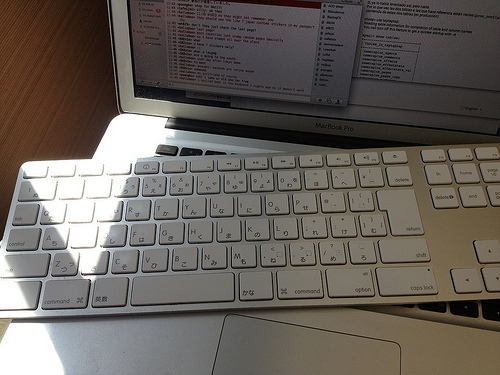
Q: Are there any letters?
A: Yes, there are letters.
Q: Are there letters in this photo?
A: Yes, there are letters.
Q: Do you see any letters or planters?
A: Yes, there are letters.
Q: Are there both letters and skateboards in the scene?
A: No, there are letters but no skateboards.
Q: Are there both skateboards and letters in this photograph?
A: No, there are letters but no skateboards.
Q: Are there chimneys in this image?
A: No, there are no chimneys.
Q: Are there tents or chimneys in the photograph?
A: No, there are no chimneys or tents.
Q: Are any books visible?
A: No, there are no books.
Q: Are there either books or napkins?
A: No, there are no books or napkins.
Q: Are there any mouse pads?
A: Yes, there is a mouse pad.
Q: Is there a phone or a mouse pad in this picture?
A: Yes, there is a mouse pad.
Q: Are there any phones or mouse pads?
A: Yes, there is a mouse pad.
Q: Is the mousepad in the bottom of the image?
A: Yes, the mousepad is in the bottom of the image.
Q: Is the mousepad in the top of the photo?
A: No, the mousepad is in the bottom of the image.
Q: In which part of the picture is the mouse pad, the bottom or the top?
A: The mouse pad is in the bottom of the image.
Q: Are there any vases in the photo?
A: No, there are no vases.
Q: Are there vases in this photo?
A: No, there are no vases.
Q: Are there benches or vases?
A: No, there are no vases or benches.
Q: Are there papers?
A: No, there are no papers.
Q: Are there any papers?
A: No, there are no papers.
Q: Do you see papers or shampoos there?
A: No, there are no papers or shampoos.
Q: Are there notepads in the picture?
A: No, there are no notepads.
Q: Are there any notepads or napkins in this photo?
A: No, there are no notepads or napkins.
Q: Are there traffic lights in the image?
A: No, there are no traffic lights.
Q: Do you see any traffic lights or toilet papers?
A: No, there are no traffic lights or toilet papers.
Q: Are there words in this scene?
A: Yes, there are words.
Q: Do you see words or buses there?
A: Yes, there are words.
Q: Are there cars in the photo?
A: No, there are no cars.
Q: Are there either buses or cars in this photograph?
A: No, there are no cars or buses.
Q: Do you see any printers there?
A: No, there are no printers.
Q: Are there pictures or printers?
A: No, there are no printers or pictures.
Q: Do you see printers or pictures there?
A: No, there are no printers or pictures.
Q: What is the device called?
A: The device is a monitor.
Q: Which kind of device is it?
A: The device is a monitor.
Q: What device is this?
A: This is a monitor.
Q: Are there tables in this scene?
A: Yes, there is a table.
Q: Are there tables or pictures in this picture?
A: Yes, there is a table.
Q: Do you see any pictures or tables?
A: Yes, there is a table.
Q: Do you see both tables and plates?
A: No, there is a table but no plates.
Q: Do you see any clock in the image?
A: No, there are no clocks.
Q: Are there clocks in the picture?
A: No, there are no clocks.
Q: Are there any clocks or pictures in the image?
A: No, there are no clocks or pictures.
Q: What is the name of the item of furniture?
A: The piece of furniture is a table.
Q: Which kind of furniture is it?
A: The piece of furniture is a table.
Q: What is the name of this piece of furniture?
A: That is a table.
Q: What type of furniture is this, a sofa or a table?
A: That is a table.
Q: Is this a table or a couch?
A: This is a table.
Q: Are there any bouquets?
A: No, there are no bouquets.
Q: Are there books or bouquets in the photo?
A: No, there are no bouquets or books.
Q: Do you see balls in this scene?
A: No, there are no balls.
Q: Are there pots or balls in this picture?
A: No, there are no balls or pots.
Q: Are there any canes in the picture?
A: No, there are no canes.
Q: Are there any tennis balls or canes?
A: No, there are no canes or tennis balls.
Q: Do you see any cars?
A: No, there are no cars.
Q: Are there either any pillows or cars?
A: No, there are no cars or pillows.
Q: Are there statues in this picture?
A: No, there are no statues.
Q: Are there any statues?
A: No, there are no statues.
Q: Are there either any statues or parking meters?
A: No, there are no statues or parking meters.